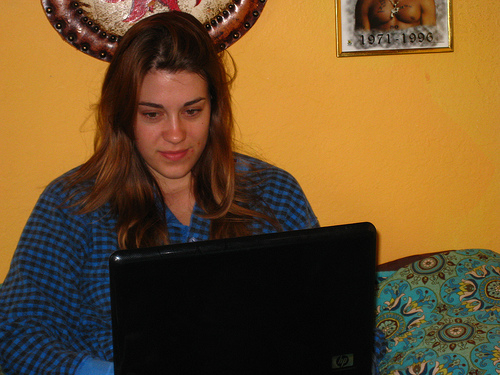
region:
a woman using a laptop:
[26, 3, 418, 373]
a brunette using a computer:
[6, 16, 421, 370]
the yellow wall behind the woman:
[321, 77, 472, 178]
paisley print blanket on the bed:
[416, 270, 484, 362]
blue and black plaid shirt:
[36, 205, 97, 308]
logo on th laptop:
[318, 337, 366, 373]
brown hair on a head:
[107, 52, 134, 111]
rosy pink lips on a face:
[159, 145, 203, 162]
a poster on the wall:
[331, 1, 457, 60]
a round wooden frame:
[46, 2, 105, 45]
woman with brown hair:
[0, 13, 321, 373]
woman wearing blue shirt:
[1, 10, 322, 374]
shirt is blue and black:
[0, 151, 387, 373]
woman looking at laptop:
[1, 11, 388, 373]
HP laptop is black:
[107, 222, 378, 373]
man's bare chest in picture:
[354, 1, 437, 34]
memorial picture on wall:
[333, 1, 453, 59]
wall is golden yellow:
[1, 1, 498, 374]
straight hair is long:
[52, 11, 286, 249]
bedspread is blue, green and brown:
[375, 247, 498, 374]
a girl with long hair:
[76, 16, 258, 276]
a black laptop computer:
[2, 172, 394, 364]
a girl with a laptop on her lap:
[99, 23, 349, 373]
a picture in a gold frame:
[313, 6, 480, 67]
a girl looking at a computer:
[85, 12, 307, 319]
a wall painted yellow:
[290, 73, 480, 184]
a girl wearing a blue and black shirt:
[47, 65, 317, 245]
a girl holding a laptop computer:
[48, 32, 318, 342]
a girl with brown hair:
[82, 35, 259, 243]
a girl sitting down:
[0, 10, 306, 353]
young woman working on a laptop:
[6, 6, 390, 373]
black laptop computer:
[113, 216, 385, 372]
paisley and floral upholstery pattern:
[379, 260, 496, 370]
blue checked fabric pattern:
[19, 240, 68, 350]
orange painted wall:
[294, 69, 476, 183]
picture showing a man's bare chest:
[336, 1, 456, 56]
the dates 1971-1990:
[342, 28, 447, 51]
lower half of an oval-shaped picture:
[34, 1, 294, 66]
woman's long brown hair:
[69, 14, 159, 255]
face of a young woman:
[131, 62, 216, 184]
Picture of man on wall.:
[345, 0, 457, 67]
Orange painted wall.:
[414, 155, 487, 257]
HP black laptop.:
[95, 185, 451, 372]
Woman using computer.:
[63, 24, 277, 332]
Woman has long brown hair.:
[71, 20, 280, 270]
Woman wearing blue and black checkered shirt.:
[48, 40, 227, 270]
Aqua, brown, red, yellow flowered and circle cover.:
[388, 229, 490, 362]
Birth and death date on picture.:
[341, 11, 461, 68]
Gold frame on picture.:
[318, 10, 427, 84]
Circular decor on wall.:
[27, 2, 274, 69]